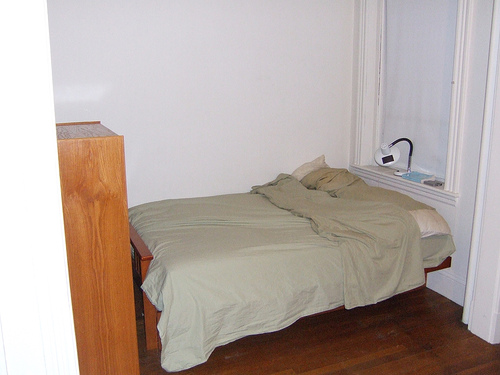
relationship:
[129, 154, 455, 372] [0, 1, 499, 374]
bed in room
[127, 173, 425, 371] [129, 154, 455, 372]
blanket on bed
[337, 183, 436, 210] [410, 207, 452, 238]
pillow case on pillow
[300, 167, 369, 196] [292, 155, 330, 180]
pillow case on pillow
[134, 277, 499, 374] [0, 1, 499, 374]
floor in room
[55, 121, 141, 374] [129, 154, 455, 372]
shelf stand at foot of bed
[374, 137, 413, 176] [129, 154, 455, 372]
lamp at head of bed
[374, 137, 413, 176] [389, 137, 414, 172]
lamp has a gooseneck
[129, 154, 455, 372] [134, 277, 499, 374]
bed above floor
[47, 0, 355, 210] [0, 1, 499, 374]
wall in room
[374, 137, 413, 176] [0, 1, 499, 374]
lamp in room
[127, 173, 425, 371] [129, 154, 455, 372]
blanket covering bed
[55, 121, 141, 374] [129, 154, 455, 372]
shelf stand next to bed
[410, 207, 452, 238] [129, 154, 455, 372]
pillow on bed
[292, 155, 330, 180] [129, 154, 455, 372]
pillow on bed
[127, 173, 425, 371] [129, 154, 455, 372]
blanket on top of bed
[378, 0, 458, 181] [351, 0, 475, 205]
shade covering window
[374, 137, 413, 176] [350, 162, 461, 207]
lamp on window sill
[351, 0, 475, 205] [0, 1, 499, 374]
window in room